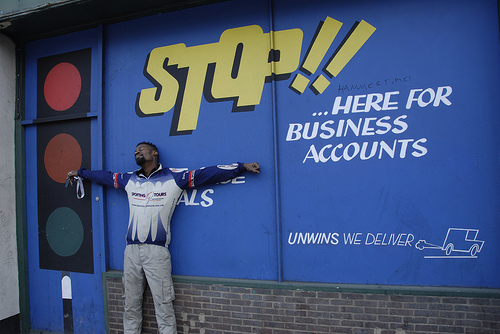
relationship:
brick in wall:
[242, 305, 286, 314] [3, 2, 500, 333]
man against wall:
[66, 140, 259, 332] [3, 2, 500, 333]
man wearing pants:
[66, 140, 259, 332] [117, 244, 179, 333]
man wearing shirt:
[66, 140, 259, 332] [82, 165, 244, 250]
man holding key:
[66, 140, 259, 332] [71, 174, 90, 198]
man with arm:
[66, 140, 259, 332] [73, 167, 135, 191]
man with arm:
[66, 140, 259, 332] [177, 164, 253, 190]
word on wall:
[126, 26, 367, 140] [3, 2, 500, 333]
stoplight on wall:
[23, 49, 101, 319] [3, 2, 500, 333]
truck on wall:
[417, 226, 485, 261] [3, 2, 500, 333]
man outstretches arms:
[66, 140, 259, 332] [72, 162, 243, 185]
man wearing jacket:
[66, 140, 259, 332] [82, 165, 244, 250]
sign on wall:
[126, 26, 367, 140] [3, 2, 500, 333]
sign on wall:
[288, 77, 459, 175] [3, 2, 500, 333]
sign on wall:
[283, 226, 415, 250] [3, 2, 500, 333]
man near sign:
[66, 140, 259, 332] [288, 77, 459, 175]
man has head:
[66, 140, 259, 332] [129, 140, 162, 174]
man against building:
[66, 140, 259, 332] [3, 2, 500, 333]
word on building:
[126, 26, 367, 140] [3, 2, 500, 333]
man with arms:
[66, 140, 259, 332] [72, 162, 243, 185]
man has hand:
[66, 140, 259, 332] [243, 156, 261, 177]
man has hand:
[66, 140, 259, 332] [67, 172, 81, 183]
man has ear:
[66, 140, 259, 332] [154, 147, 160, 159]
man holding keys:
[66, 140, 259, 332] [71, 174, 90, 198]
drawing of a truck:
[417, 226, 485, 261] [401, 211, 494, 275]